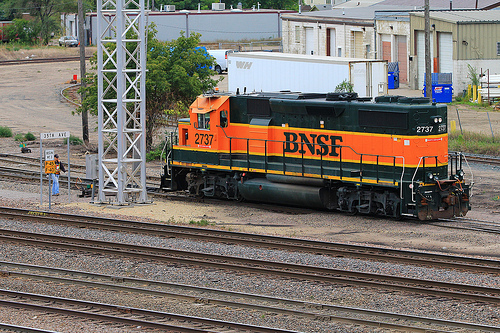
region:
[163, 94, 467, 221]
a dark black and orange train car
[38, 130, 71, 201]
three street signs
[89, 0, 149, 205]
a tall white tower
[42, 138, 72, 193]
a person under a sign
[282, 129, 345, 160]
black words on a train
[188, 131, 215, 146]
black numbers on a train car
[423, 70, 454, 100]
a large blue dumpster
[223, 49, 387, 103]
a large white truck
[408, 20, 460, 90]
a close white garage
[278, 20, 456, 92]
a row of closed garages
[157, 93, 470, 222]
Orange and black train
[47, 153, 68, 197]
Rail worker in black cap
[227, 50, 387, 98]
White truck cargo container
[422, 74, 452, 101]
Blue metal trash bin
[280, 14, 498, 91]
Line of storage units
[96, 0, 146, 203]
Tall white metal structure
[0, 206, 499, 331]
Railroad tracks running parallel to each other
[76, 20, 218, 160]
Green tree near rail tracks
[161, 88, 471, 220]
Train with number 2737 painted by front window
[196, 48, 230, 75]
Back part of a white van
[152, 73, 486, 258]
The train is black and orange.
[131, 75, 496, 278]
The train is on a track.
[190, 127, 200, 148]
The number is black.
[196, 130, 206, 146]
The number is black.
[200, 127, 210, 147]
The number is black.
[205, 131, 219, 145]
The number is black.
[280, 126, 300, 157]
The letter is black.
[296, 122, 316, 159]
The letter is black.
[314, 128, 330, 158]
The letter is black.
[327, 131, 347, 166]
The letter is black.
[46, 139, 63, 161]
head of a person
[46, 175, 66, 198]
legs of a person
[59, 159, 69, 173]
arm of a person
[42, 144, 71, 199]
person walking on road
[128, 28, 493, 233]
a orange train on rail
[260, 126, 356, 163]
characters on train body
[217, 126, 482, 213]
hand rails on train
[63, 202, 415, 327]
bunch of rail roads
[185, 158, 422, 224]
wheels of a train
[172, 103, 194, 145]
door of a train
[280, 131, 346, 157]
railcar has BNSF logo on the side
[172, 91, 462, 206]
railcar is painted black and orange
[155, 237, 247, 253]
gravel lying between railroad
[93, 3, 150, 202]
metal tower beside railroad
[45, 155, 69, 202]
person walking beside railroad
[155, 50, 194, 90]
tree has green leaves on it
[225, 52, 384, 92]
white tractor trailer behind railcar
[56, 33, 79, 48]
car in background is silver in color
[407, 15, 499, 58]
brown building in background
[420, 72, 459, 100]
blue trash dumpster in background